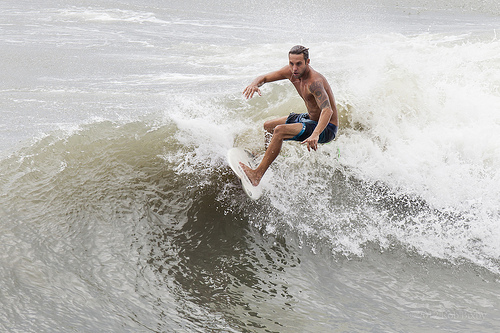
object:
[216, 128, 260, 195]
surfboard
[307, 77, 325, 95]
shoulder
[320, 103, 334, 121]
elbow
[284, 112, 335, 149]
swimsuit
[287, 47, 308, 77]
head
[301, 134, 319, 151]
hand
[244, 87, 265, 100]
hand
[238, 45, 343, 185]
man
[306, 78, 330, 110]
tattoo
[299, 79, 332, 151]
arm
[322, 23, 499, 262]
waves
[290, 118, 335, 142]
trouser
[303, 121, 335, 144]
black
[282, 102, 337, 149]
blue shorts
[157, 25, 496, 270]
wave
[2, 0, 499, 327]
ocean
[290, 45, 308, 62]
hair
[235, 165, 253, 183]
letters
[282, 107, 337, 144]
trunks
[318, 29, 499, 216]
white waves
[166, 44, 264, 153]
white waves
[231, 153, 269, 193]
foot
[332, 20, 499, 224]
froth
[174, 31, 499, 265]
wave crest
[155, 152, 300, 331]
reflection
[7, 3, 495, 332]
water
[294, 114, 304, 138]
trim